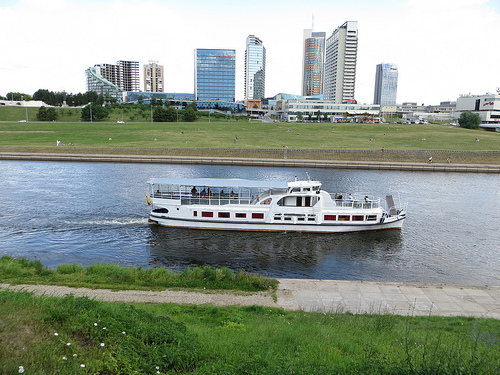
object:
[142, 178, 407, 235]
boat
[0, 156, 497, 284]
river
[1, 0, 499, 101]
sky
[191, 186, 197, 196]
person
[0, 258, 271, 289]
grass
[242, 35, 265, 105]
buidling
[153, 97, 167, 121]
tree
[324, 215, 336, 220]
window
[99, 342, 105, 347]
flower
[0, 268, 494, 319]
sidewalk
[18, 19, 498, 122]
city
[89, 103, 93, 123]
post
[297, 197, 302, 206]
door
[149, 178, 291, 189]
canopy